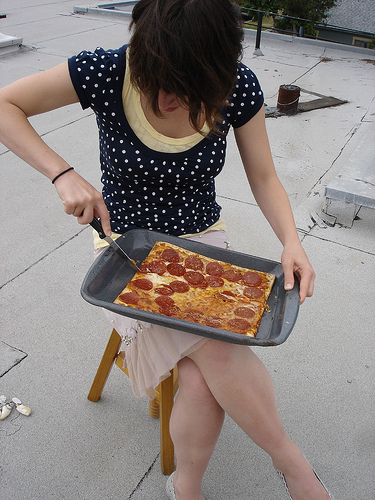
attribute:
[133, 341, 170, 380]
skirt — white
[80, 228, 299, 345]
pan — black 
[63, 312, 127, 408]
leg — chair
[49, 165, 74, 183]
bracelet — black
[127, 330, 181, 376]
skirt — beige 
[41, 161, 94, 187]
bracelet — Black 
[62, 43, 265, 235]
shirt — black , blue,  polka dot, blue and white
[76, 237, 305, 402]
skirt — pink with ruffles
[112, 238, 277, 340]
pizza — large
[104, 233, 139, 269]
part — silver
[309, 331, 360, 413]
cement — gray 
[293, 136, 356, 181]
sidewalk — gray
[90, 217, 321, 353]
pan — gray 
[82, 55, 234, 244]
undershirt — Yellow 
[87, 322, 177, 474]
chair — wooden 